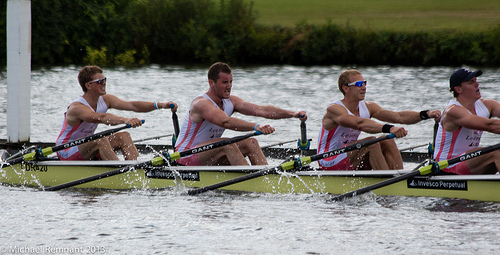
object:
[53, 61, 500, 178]
team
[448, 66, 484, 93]
hat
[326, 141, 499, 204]
oars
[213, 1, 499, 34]
grass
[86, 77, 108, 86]
sunglasses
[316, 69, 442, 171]
man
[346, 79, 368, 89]
sunglasses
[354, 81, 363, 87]
lens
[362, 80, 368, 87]
lens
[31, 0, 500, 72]
bush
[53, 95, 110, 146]
shirt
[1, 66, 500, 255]
wake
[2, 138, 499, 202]
boat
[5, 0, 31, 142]
pole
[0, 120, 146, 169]
oar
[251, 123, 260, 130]
wrists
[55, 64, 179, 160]
man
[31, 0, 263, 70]
trees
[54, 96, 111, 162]
uniform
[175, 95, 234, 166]
uniform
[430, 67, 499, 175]
man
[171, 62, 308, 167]
man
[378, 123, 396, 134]
sweatbands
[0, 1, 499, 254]
background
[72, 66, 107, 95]
hair